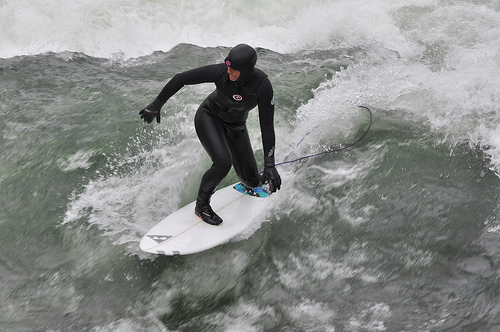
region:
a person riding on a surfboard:
[105, 45, 303, 249]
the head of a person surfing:
[219, 40, 257, 89]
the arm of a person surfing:
[135, 60, 227, 120]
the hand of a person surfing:
[135, 100, 167, 132]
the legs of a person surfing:
[187, 103, 263, 225]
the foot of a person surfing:
[188, 185, 231, 223]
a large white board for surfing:
[140, 163, 267, 270]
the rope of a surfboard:
[323, 88, 387, 163]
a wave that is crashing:
[15, 10, 71, 67]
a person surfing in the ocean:
[140, 56, 286, 238]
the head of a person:
[219, 45, 257, 88]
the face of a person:
[225, 59, 244, 81]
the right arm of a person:
[118, 63, 218, 119]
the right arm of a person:
[135, 105, 162, 125]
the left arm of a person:
[255, 91, 292, 191]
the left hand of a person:
[258, 164, 284, 195]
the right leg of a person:
[190, 104, 224, 225]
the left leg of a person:
[221, 121, 264, 192]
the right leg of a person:
[186, 193, 221, 227]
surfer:
[134, 25, 312, 285]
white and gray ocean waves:
[340, 239, 437, 304]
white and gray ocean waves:
[384, 168, 452, 240]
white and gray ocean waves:
[261, 269, 321, 323]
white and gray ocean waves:
[181, 252, 256, 302]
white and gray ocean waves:
[32, 241, 102, 282]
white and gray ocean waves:
[58, 128, 98, 162]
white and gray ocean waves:
[372, 42, 472, 119]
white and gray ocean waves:
[305, 45, 395, 89]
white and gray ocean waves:
[14, 23, 88, 117]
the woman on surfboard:
[113, 45, 322, 299]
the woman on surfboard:
[110, 34, 292, 256]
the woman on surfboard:
[111, 19, 301, 304]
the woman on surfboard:
[112, 22, 342, 294]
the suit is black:
[130, 60, 289, 228]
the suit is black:
[134, 57, 261, 207]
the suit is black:
[141, 74, 295, 232]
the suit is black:
[145, 37, 292, 228]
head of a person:
[219, 31, 264, 78]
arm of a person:
[153, 42, 221, 119]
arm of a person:
[249, 110, 293, 167]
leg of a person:
[195, 142, 235, 207]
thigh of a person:
[229, 114, 269, 170]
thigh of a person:
[192, 104, 234, 156]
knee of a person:
[208, 144, 263, 171]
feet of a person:
[185, 193, 242, 233]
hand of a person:
[119, 111, 174, 133]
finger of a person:
[120, 102, 170, 132]